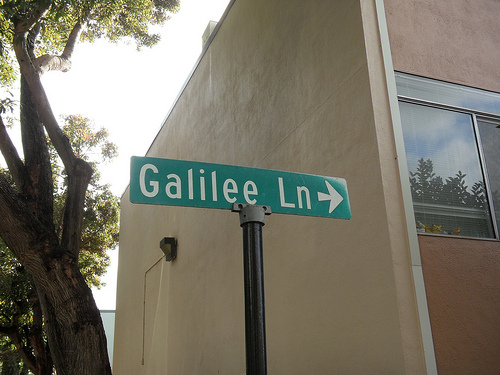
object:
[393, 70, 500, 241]
window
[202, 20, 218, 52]
unit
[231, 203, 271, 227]
metal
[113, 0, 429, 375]
ground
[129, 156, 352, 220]
sign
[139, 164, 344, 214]
letters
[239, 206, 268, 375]
metal pole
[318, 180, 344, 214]
arrow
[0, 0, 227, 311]
sky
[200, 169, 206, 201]
letter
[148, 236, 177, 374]
wire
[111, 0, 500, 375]
building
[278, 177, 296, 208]
letter l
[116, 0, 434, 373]
wall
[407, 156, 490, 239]
tree refected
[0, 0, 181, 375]
tree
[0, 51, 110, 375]
trunk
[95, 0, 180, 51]
leaves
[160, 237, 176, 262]
holder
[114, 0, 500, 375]
apartment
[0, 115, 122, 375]
leaves